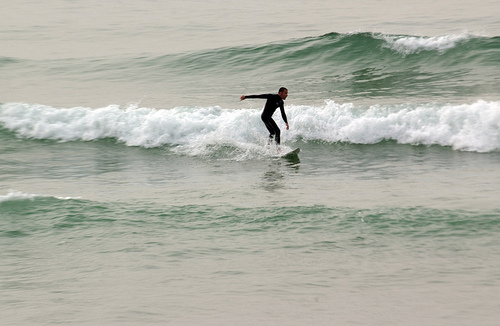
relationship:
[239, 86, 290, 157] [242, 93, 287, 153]
surfer wearing wetsuit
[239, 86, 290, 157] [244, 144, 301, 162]
surfer on surfboard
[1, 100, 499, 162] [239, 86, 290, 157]
wave behind surfer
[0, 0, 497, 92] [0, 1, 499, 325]
water in ocean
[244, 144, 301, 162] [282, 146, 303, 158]
surfboard has front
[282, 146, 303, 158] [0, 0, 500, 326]
front sticking out of water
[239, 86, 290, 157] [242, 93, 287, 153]
surfer in wetsuit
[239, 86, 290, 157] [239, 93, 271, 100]
surfer has arm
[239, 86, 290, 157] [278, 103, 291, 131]
surfer has arm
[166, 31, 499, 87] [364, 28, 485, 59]
wave has top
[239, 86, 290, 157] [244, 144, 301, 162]
surfer on top of surfboard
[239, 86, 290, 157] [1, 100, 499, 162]
surfer riding wave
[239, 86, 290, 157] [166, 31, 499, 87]
surfer in front of wave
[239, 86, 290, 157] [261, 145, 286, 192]
surfer has reflection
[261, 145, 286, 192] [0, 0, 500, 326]
reflection in water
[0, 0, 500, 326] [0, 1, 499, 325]
water in ocean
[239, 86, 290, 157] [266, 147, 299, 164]
surfer has edge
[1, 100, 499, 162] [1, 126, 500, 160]
wave has edge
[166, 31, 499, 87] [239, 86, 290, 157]
wave behind surfer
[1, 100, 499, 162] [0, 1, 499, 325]
wave on ocean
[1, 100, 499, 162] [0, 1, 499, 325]
wave in ocean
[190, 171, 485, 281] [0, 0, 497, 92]
part of water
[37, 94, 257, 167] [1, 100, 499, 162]
part of wave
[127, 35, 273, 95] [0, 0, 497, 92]
part of water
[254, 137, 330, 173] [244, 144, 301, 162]
part of surfboard